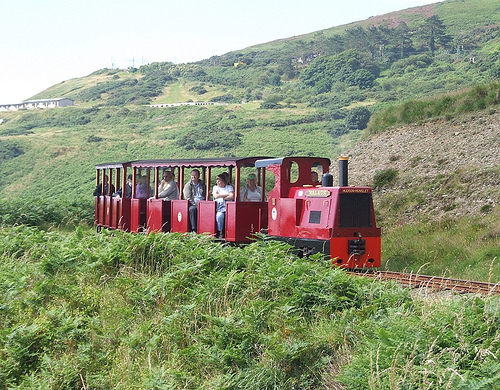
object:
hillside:
[0, 0, 499, 286]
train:
[92, 155, 381, 274]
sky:
[0, 0, 444, 105]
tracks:
[376, 270, 500, 290]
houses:
[47, 96, 75, 108]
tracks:
[344, 271, 500, 296]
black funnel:
[337, 156, 349, 186]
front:
[331, 187, 382, 269]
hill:
[21, 68, 247, 102]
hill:
[186, 0, 500, 64]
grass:
[0, 223, 500, 390]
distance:
[0, 0, 499, 85]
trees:
[403, 65, 414, 74]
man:
[182, 168, 206, 232]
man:
[149, 170, 180, 203]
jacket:
[183, 178, 207, 207]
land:
[0, 0, 500, 390]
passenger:
[211, 174, 234, 238]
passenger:
[93, 174, 115, 197]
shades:
[163, 176, 167, 178]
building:
[0, 96, 75, 113]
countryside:
[0, 54, 499, 115]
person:
[135, 175, 152, 199]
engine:
[254, 155, 382, 270]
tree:
[269, 93, 282, 104]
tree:
[282, 96, 296, 107]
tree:
[354, 68, 376, 90]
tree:
[391, 20, 415, 57]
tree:
[414, 14, 454, 52]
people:
[240, 173, 268, 202]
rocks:
[455, 131, 460, 136]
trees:
[129, 67, 138, 73]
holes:
[367, 258, 375, 264]